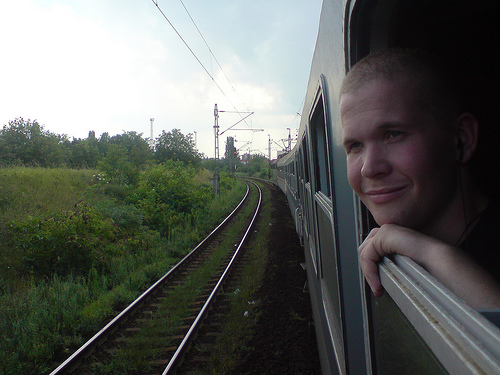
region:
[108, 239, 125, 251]
part of a bush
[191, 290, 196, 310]
part of a rail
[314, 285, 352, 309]
side of a train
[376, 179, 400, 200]
mouth of a man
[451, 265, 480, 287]
part of an hand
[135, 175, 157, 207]
part of a forest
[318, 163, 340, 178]
side of a train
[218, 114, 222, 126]
part of a post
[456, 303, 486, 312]
edge of a window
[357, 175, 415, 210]
mouth of a person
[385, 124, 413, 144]
eye of a person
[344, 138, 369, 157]
eye of a person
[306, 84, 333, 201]
window on a train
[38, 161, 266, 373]
metal train tracks near a train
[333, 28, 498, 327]
person leaning out a train window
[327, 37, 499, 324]
person with short hair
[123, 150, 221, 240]
green bush near train tracks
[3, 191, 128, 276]
green bush near train tracks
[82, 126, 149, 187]
green bush near train tracks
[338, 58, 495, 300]
a man sticking his head out a wondow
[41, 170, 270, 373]
a set of railroad tracks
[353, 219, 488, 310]
a man's hand holding on to a window ledge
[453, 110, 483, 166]
a mans ear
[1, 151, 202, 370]
a bunch of green bushy buches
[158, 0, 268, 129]
a pair of power lines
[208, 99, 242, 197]
a power line pole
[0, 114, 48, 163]
a leafy tree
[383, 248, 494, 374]
dirt in a window frame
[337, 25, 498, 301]
a man smiling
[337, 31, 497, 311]
this is a person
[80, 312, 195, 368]
this is a railway line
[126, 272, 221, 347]
this is a railway line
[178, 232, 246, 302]
this is a railway line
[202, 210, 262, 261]
this is a railway line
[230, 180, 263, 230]
this is a railway line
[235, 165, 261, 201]
this is a railway line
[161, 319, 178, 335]
part of a rail way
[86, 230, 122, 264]
part of the grass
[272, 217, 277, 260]
side of a train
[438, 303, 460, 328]
edge of a window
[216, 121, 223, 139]
part of a pole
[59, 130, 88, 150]
part of a forest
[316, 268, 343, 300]
side of a train